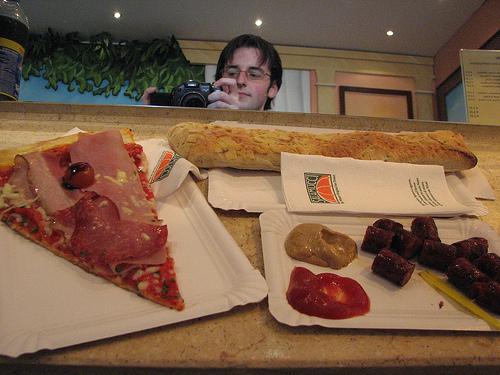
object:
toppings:
[122, 261, 178, 304]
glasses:
[142, 34, 284, 111]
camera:
[151, 80, 217, 109]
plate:
[256, 209, 500, 330]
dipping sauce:
[284, 264, 371, 320]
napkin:
[278, 151, 471, 219]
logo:
[302, 170, 344, 205]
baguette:
[167, 120, 478, 173]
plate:
[203, 119, 486, 215]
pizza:
[0, 127, 191, 310]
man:
[142, 33, 282, 112]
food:
[1, 119, 498, 322]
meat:
[67, 128, 137, 206]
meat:
[72, 219, 173, 260]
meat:
[10, 152, 73, 214]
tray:
[0, 134, 256, 362]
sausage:
[419, 239, 457, 270]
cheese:
[54, 217, 75, 233]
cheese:
[212, 137, 235, 155]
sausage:
[444, 253, 500, 312]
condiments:
[283, 219, 357, 270]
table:
[0, 100, 500, 375]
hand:
[136, 86, 157, 106]